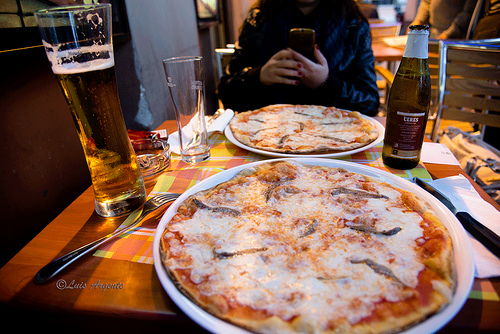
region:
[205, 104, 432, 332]
two pizzas on plates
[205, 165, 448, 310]
pizza has brown crust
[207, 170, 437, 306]
pizza has orange sauce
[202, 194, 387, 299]
pizza has white cheese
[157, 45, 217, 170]
clear and empty glass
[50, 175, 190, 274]
steel fork next to plate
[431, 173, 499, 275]
white napkin under knife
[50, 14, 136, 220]
large glass with beer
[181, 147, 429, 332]
plate on brown table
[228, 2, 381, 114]
person has blue coat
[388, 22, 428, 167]
beverage bottle is open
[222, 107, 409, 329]
two dishes of pizza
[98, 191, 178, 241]
fork is turned over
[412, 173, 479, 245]
knife on a napkin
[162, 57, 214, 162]
the glass is empty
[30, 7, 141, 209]
glass is almost full of beverage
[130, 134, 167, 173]
ashtray on the table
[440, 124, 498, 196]
yellow tote by the table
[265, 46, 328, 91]
wearing red nail polish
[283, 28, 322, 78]
holding a phone with both hands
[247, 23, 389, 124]
a person using a cell hone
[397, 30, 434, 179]
a bottle of beer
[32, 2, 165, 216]
a glass of amber colored beer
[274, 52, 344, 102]
red painted finger nails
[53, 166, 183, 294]
a fork upside down on the table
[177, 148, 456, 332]
a pizza on a serving plate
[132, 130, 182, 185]
a glass ashtray on the table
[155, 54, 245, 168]
an empty beer glass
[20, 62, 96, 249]
the back of the booth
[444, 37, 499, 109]
a metal and wooden chair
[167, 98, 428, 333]
Two large vegetarian pizzas.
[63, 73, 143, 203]
A glass of beer.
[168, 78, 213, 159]
An empty and clear glass.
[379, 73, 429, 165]
An empty beer bottle.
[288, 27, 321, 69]
A black cell phone.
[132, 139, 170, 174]
A round cigarette ashtray.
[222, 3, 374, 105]
A lady using her cell phone.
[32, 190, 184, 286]
A fork next to the pizza.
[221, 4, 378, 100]
A lady wearing blue blouse.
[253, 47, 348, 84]
Dark red nail polish.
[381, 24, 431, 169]
a bottle of beer on the table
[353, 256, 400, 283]
anchovies on the pizza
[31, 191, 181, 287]
a fork on the table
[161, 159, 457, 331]
a thin crust pizza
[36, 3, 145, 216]
a glass of beer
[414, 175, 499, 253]
the knife has a black handle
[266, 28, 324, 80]
a cell phone in the girl's hand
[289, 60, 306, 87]
red finger nail polish